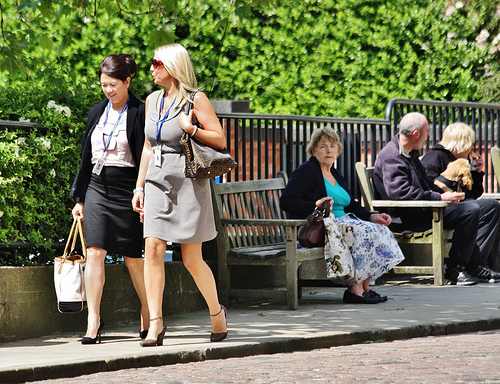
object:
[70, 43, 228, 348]
women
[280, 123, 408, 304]
woman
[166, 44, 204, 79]
hair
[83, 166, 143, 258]
skirt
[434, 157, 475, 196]
dog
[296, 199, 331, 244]
bag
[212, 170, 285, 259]
bench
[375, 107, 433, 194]
man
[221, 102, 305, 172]
railing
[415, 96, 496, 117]
fence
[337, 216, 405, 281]
skirt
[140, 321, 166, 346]
shoe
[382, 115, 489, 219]
people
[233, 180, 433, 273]
benches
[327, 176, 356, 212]
shirt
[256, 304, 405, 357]
sidewalk